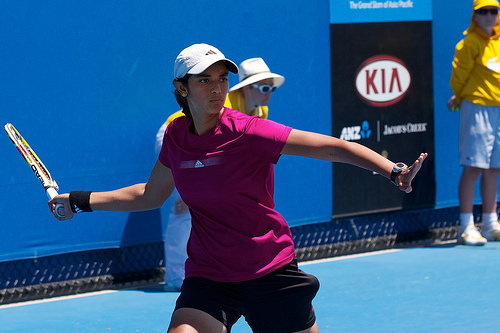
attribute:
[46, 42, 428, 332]
woman — concentrating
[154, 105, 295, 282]
shirt — pink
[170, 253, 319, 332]
shorts — black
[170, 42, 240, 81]
cap — light colored, white, adidas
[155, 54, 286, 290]
man — line judge, bending forward, bending over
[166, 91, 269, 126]
shirt — yellow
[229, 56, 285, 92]
hat — white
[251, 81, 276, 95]
sunglasses — white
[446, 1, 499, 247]
man — standing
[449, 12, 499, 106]
sweatshirt — yellow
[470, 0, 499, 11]
cap — yellow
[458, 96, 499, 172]
shorts — gray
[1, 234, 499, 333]
court — color blue, blue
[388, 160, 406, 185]
watch — black, chrome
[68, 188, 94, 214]
wristband — black, thick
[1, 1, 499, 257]
wall — blue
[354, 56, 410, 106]
decal — red, white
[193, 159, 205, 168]
triangle — white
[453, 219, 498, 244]
shoes — white, yellow